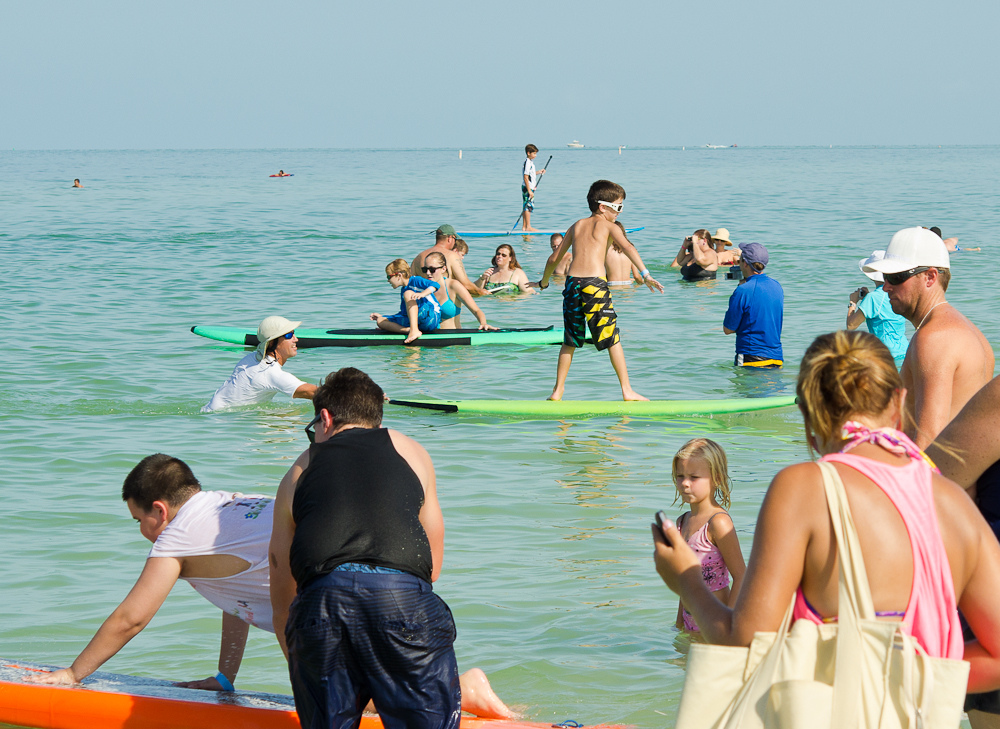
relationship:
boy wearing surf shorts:
[29, 448, 528, 724] [551, 270, 627, 355]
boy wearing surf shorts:
[263, 362, 466, 725] [551, 270, 627, 355]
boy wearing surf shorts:
[534, 177, 665, 399] [551, 270, 627, 355]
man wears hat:
[861, 221, 998, 461] [855, 219, 955, 281]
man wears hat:
[713, 227, 791, 373] [728, 232, 777, 279]